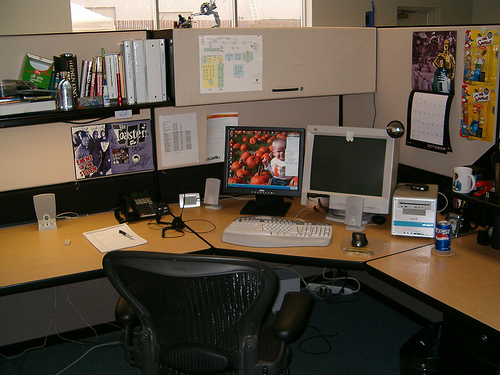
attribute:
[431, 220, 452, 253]
soda can — pepsi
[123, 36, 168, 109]
binders — white 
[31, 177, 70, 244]
speaker — white, volume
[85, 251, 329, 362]
chair — black, office, desk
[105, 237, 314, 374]
chair — black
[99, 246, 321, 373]
chair — black, office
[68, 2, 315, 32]
window — open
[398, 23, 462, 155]
calendar — wall, Star Wars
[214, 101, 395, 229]
monitors — lit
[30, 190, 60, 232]
speaker — gray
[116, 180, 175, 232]
phone — office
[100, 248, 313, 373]
office chair — black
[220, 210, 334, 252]
keyboard — computer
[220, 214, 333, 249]
keyboard — computer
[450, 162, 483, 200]
mug — white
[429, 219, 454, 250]
bottle — soda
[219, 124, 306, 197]
monitor — computer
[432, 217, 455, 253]
can — small, soda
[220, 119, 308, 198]
trim — black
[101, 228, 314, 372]
desk chair — black , ergonomic 